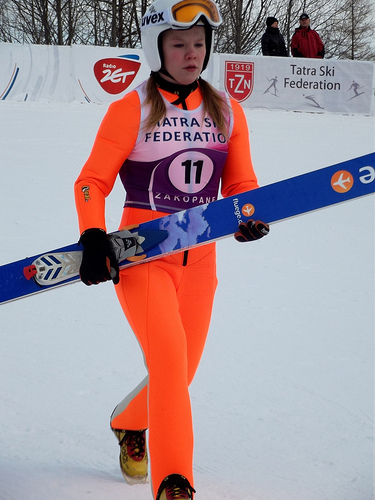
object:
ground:
[0, 173, 372, 496]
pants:
[110, 207, 218, 499]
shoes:
[156, 475, 193, 500]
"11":
[181, 159, 204, 184]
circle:
[168, 151, 215, 194]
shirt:
[73, 82, 260, 263]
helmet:
[140, 0, 223, 73]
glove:
[78, 228, 120, 287]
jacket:
[291, 26, 326, 59]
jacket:
[261, 28, 288, 57]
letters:
[144, 116, 226, 143]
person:
[73, 0, 270, 500]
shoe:
[110, 418, 148, 486]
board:
[0, 152, 375, 307]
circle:
[331, 170, 354, 194]